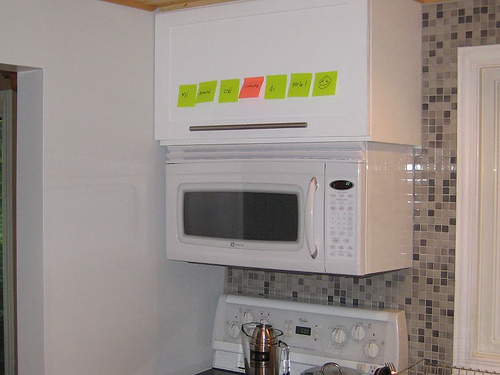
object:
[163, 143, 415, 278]
microwave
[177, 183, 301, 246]
glass door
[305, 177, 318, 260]
handle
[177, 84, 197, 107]
post it note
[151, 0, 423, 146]
cabinet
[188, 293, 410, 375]
stove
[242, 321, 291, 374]
measuring cup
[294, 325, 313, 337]
display panel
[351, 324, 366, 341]
control knobs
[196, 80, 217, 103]
sticky note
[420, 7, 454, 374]
tile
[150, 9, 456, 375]
wall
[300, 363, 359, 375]
lid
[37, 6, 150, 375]
wall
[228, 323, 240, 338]
knob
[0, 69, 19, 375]
door frame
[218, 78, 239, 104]
post it note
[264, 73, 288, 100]
post it note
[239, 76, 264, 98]
sticky note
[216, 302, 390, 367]
oven control panel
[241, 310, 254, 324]
knob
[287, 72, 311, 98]
post it note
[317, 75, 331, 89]
smiley face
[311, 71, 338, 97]
post it note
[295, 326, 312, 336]
screen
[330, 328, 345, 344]
dial